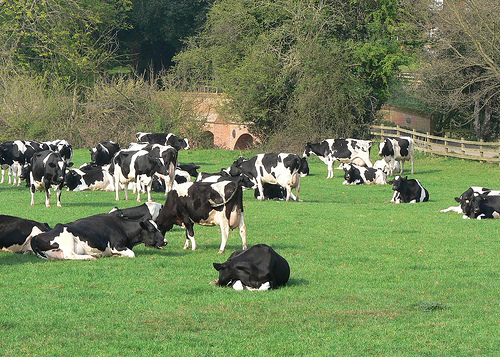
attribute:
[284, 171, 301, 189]
udder — pink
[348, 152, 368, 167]
udder — pink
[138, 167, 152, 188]
udder — pink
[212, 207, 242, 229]
udder — pink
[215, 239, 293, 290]
cow — black, white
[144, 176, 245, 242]
cow — white, black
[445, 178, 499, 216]
cow — white, black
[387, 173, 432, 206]
cow — white, black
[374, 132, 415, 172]
cow — white, black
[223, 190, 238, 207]
cow's tail — white, black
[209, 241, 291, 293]
cow — lying, black, white, sleeping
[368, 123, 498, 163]
fence — wood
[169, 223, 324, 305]
cow — black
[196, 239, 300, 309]
cow — white, black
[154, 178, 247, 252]
cow — black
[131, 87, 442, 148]
bridge — brick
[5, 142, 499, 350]
grass — green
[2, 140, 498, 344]
field — grass field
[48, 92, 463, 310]
field — grassy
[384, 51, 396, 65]
leaf — green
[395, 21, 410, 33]
leaf — green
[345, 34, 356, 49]
leaf — green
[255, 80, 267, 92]
leaf — green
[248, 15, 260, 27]
leaf — green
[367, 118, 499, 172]
fence — wooden, brown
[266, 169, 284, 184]
spot — white, black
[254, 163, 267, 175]
spot — white, black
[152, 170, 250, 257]
cow — white, black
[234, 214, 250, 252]
leg — back leg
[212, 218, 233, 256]
leg — back leg